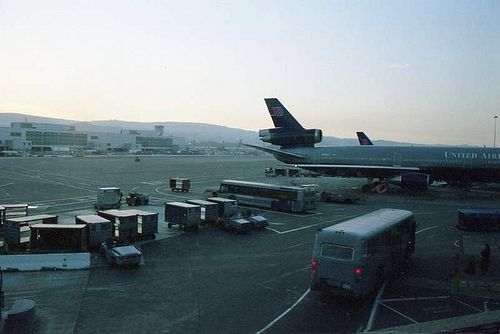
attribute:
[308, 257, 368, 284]
lights — round, red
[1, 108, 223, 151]
buildings — many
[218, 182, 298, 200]
windows — many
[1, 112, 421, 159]
mountains — in the distance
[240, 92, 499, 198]
airline — parked, large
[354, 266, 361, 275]
lights — back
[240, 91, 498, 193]
plane — huge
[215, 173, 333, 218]
bus — parked, long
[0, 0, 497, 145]
sky — overcast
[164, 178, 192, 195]
carrier — luggage, empty